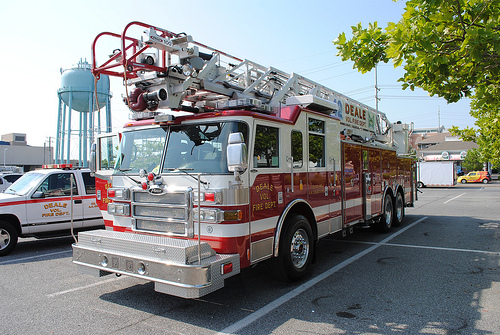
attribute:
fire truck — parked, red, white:
[68, 19, 421, 299]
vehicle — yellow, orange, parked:
[454, 170, 493, 184]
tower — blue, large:
[56, 58, 113, 168]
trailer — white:
[417, 159, 458, 189]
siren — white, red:
[43, 162, 75, 170]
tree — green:
[332, 2, 500, 173]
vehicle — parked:
[0, 164, 107, 255]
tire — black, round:
[268, 206, 316, 285]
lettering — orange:
[251, 182, 278, 213]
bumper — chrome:
[65, 227, 241, 300]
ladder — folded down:
[90, 20, 396, 147]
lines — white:
[2, 243, 499, 335]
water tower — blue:
[53, 55, 117, 172]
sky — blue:
[2, 0, 498, 159]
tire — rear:
[370, 187, 396, 236]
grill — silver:
[129, 187, 192, 238]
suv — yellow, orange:
[455, 170, 492, 185]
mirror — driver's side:
[227, 131, 248, 174]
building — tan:
[403, 130, 483, 188]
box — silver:
[74, 227, 219, 263]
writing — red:
[343, 102, 367, 129]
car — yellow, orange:
[456, 170, 491, 185]